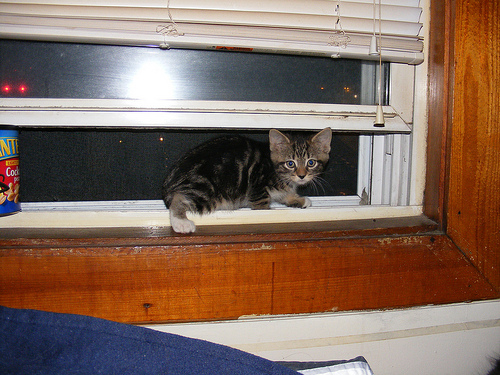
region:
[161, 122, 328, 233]
the kitten on the window sill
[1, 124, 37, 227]
the can of nuts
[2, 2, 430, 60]
the blinds are up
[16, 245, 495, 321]
the window frame is wooden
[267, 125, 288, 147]
the ear of the kitten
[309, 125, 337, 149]
the ear of the kitten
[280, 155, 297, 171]
the eye of the kitten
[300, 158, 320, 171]
the eye of the kitten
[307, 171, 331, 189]
whiskers on the kitten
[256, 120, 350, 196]
the head of the kitten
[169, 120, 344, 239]
"A kitten is pictured here"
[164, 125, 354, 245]
"The kitten is looking toward the camera"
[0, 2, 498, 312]
"The kitten is sitting in the window"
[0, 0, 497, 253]
"The window is slightly opened"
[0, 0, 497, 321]
"A wood frame is around the window"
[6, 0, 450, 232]
"Blinds are in the window"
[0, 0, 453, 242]
"The window blinds are white"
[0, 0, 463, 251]
"The window blinds are up"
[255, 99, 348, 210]
"The kitten has blue eyes"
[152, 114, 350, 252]
"The kitten is black, gray and white"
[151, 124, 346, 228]
this is a cat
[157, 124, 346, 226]
the cat is grey in color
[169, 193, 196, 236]
this is the leg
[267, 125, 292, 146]
this is an ear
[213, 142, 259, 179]
the cat is grey in color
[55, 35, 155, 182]
this is the window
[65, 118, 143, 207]
the window is half closed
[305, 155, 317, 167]
this is the eye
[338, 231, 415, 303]
this is a frame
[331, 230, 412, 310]
the frame is wooden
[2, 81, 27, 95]
Red lights outside window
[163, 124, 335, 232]
Cat sitting on windowsill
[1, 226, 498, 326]
Worn wood on side of window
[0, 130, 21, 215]
Can of nuts on windowsill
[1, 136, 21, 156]
Yellow brand name on blue and red can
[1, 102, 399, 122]
White paint peeling and chipping on window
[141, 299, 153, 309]
Black knot on wood near windowsill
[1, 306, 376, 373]
Blue and white bedding near window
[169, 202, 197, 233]
White cat paw touching wood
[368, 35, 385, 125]
Plastic pull for blinds